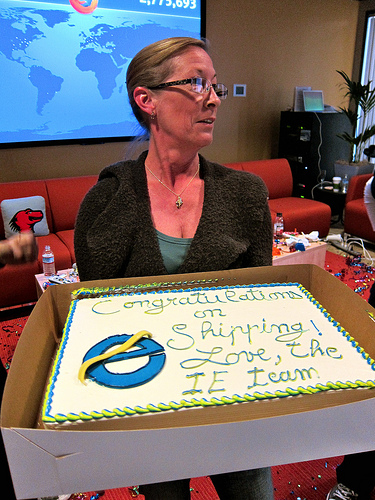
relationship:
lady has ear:
[71, 30, 274, 285] [129, 85, 156, 118]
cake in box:
[37, 279, 374, 431] [0, 264, 372, 499]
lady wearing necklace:
[71, 30, 274, 285] [127, 135, 214, 220]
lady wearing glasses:
[71, 30, 274, 285] [133, 71, 235, 100]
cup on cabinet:
[318, 165, 347, 192] [269, 87, 361, 209]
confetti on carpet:
[264, 441, 327, 497] [0, 299, 363, 485]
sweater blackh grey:
[84, 204, 265, 250] [220, 194, 258, 268]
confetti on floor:
[86, 452, 355, 498] [86, 452, 368, 497]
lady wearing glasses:
[71, 30, 274, 285] [124, 73, 234, 114]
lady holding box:
[71, 30, 274, 285] [10, 274, 373, 468]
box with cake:
[10, 274, 373, 468] [37, 279, 374, 431]